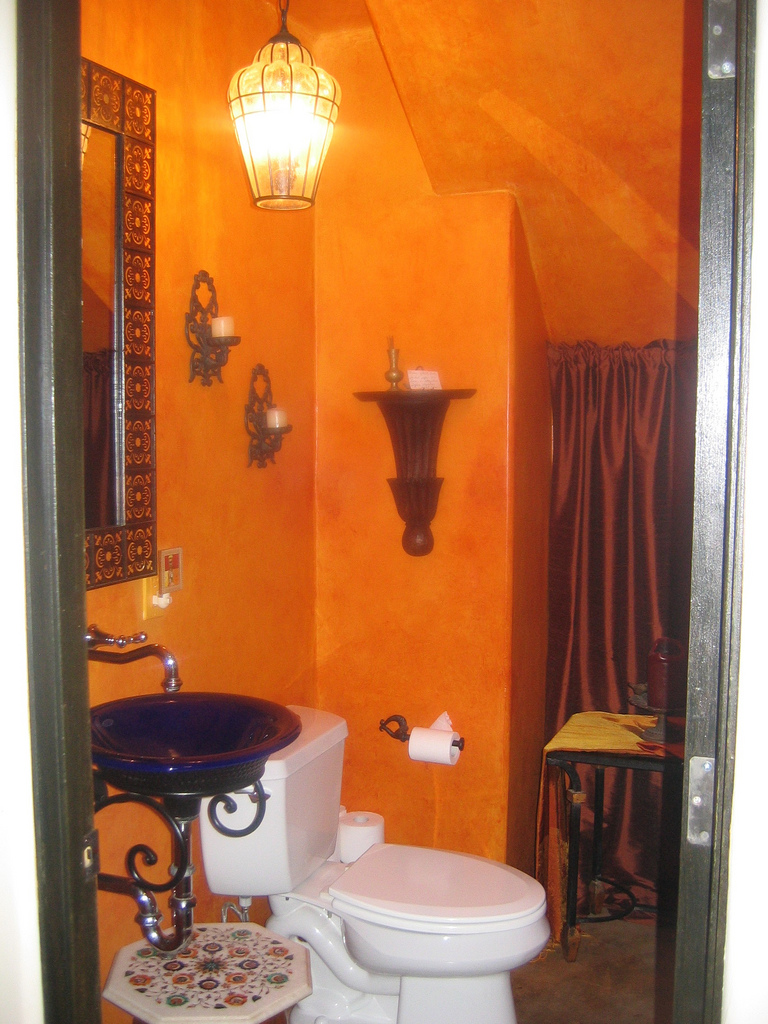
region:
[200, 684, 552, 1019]
THE TOILET IS WHITE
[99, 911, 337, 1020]
THE TABLE TOP IS AN OCTAGON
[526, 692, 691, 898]
THE TABLE HAS A YELLOW CLOTH ON IT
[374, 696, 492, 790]
THE TOILET PAPER IS ON THE WALL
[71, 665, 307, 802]
THE SINK IS BLUE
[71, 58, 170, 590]
THE MIRROR IS ON THE WALL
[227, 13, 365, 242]
THE LIGHT IS ON THE CEILING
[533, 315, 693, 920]
THE CURTAIN IS DARK BROWN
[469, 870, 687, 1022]
THE FLOOR IS BROWN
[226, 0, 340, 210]
the light fixture is hanging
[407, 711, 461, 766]
the roll of toilet paper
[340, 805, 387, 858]
the toilet paper is white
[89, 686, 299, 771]
the sink is dark blue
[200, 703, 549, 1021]
the toilet is white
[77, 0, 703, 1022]
the bathroom ceiling and walls are orange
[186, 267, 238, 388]
the candle in the candle holder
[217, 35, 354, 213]
a light is hanging from the ceiling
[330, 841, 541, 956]
the toilet lid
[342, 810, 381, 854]
a roll of toilet paper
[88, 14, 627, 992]
the wall is orange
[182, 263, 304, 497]
candles are on the wall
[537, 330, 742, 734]
a red curtain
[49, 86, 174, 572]
it is a mirror on the wall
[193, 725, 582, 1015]
it is a white toilet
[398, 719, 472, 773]
a roll of paper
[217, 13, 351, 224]
A light is turned on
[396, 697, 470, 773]
A roll of toilet paper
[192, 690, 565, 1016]
A white porcelain toilet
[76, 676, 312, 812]
A round black sink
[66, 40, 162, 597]
A mirror hanging on the wall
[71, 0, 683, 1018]
Walls have been painted mustard yellow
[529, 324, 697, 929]
The curtains are brown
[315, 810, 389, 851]
toilet paper on the toilet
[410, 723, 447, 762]
toilet paper on the roll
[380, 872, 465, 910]
lid of the toilet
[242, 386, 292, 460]
candle on the wall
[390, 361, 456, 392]
candle on the wall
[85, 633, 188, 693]
sink on the wall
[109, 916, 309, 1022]
small table with a flower patterned top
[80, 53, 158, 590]
large mirror hanging on a wall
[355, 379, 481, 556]
wooden shelf on a wall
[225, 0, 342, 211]
Turned on lamppost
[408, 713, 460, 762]
Rolled up toliet paper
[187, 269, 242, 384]
Non lit up candle on the wall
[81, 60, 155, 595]
Mirror with patterned frame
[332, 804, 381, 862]
Stack of toliet paper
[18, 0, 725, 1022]
Opened door to bathroom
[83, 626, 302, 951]
Blue sink with faucet in the wall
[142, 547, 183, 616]
Outlet with charger plugged in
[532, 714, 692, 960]
Black table with cloth on it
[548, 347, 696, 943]
Long red curtains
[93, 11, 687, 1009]
orange painted wall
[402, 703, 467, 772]
white roll of toilet paper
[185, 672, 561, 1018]
white ceramic toilet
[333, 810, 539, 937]
white toilet lid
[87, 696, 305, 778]
round blue stone sink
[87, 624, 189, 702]
silver metal faucet above sink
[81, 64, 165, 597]
colorful mirror frame on wall